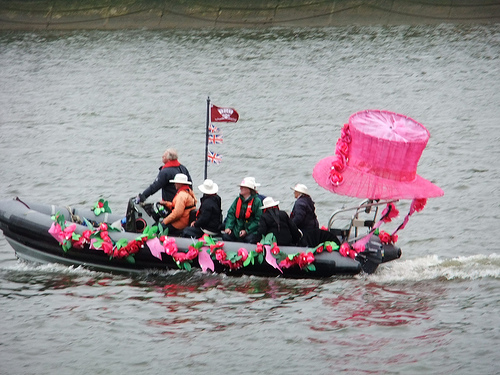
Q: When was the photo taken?
A: Daytime.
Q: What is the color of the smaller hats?
A: White.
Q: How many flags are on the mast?
A: 4.